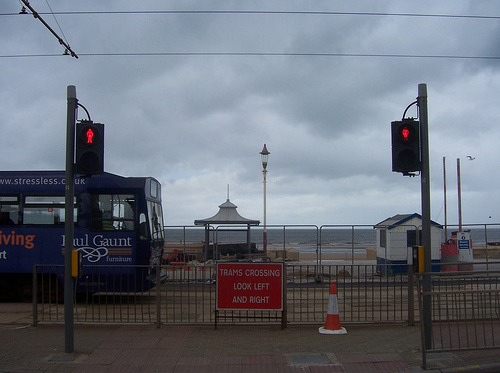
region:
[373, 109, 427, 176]
the traffic light on a pole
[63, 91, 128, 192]
the traffic light on a pole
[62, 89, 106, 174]
the light is red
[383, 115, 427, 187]
the light is red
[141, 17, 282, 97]
the sky is cloudy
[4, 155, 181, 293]
the tram on the tracks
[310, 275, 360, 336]
the traffic cone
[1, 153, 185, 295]
the tram is blue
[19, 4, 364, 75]
power cables above the tram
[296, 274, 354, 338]
the traffic cone is orange and white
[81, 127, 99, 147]
red pedestrian sign on a traffic signal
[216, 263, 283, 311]
red and white sign in front of a fence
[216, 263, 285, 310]
red and white trams crossing sign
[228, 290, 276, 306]
white text on a red sign reading AND RIGHT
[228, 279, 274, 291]
white text on a red sign reading LOOK LEFT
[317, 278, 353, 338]
a cone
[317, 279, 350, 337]
orange and white cone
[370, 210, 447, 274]
small white and blue building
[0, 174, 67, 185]
white print on a royal blue bus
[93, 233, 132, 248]
white bus print reading Gaunt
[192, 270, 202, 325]
metal post on gate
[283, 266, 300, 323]
metal post on gate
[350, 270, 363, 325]
metal post on gate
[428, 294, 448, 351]
metal post on gate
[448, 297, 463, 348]
metal post on gate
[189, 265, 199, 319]
metal post on gate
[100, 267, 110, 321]
metal post on gate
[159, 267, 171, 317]
metal post on gate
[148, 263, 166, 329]
metal post on gate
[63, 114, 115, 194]
a traffic signal indicator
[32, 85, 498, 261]
set of traffic signals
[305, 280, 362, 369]
a warning board on road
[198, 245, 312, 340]
a board placed on road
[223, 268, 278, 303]
white text written in board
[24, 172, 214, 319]
a part of the bus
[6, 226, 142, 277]
advertisement displayed on bus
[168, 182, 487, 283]
a group of homes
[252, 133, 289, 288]
a long electric poll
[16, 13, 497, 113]
a small thin electric wires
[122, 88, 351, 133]
Sky is grey color.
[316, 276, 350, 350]
Cone is orange and white color.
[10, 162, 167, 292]
Bus is in road.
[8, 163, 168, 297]
Bus is blue color.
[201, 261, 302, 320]
Board is attached to the fence.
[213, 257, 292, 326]
Board is red and white color.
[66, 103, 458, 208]
Signals are attached to the pole.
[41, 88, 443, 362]
Pole is in sidewalk.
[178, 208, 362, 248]
Water is blue color.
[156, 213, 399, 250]
Water is behind the bus.